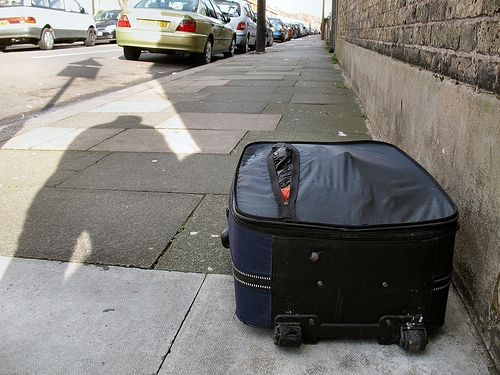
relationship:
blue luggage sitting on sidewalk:
[219, 139, 461, 353] [11, 9, 471, 371]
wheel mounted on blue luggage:
[402, 322, 430, 353] [219, 139, 461, 353]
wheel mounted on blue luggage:
[273, 322, 300, 347] [219, 139, 461, 353]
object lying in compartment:
[278, 185, 292, 200] [236, 138, 452, 219]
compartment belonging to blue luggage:
[236, 138, 452, 219] [219, 139, 461, 353]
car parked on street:
[115, 0, 235, 67] [10, 46, 115, 83]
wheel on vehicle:
[23, 16, 73, 53] [3, 1, 100, 53]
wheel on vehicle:
[79, 15, 101, 47] [3, 1, 100, 53]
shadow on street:
[45, 50, 106, 110] [1, 41, 182, 122]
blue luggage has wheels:
[219, 139, 461, 353] [273, 296, 440, 362]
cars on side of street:
[117, 1, 339, 56] [0, 42, 175, 115]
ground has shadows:
[38, 62, 240, 279] [11, 81, 198, 231]